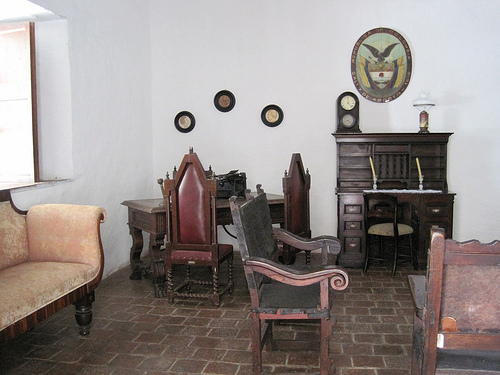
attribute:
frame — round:
[175, 110, 193, 131]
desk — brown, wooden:
[333, 130, 454, 272]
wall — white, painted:
[86, 21, 246, 103]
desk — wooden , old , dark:
[327, 117, 473, 290]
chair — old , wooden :
[154, 143, 239, 308]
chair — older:
[217, 193, 348, 371]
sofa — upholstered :
[0, 174, 106, 343]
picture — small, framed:
[168, 110, 195, 133]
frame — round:
[258, 102, 288, 130]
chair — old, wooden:
[227, 181, 347, 372]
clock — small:
[332, 90, 362, 133]